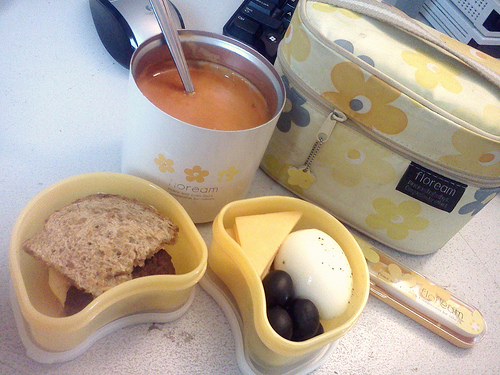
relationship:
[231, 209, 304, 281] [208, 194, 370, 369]
cheese in container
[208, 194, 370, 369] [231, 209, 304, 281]
container has cheese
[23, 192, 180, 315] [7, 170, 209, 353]
sandwich in container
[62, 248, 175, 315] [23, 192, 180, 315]
meat on sandwich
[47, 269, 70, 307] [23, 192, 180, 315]
egg on sandwich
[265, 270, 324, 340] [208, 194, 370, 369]
olives in container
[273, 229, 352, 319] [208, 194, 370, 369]
boiled egg in container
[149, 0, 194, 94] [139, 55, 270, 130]
spoon in soup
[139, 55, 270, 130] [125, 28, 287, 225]
soup in thermos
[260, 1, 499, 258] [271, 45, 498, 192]
lunch box has a zipper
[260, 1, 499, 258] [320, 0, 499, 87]
lunch box has a handle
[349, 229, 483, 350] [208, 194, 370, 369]
utensils are beside container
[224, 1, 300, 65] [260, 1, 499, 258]
keyboard behind lunch box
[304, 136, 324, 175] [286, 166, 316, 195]
chain on charm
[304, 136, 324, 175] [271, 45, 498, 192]
chain attached to zipper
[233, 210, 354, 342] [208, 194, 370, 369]
food in container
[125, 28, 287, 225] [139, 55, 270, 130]
thermos has soup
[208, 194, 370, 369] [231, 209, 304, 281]
container contains cheese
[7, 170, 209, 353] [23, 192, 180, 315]
container contains sandwich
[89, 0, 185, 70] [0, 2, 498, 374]
mouse on table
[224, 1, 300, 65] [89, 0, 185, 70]
keyboard beside mouse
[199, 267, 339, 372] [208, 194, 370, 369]
lid under container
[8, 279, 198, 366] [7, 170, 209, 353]
lid under container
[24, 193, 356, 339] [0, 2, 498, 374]
food sitting on table